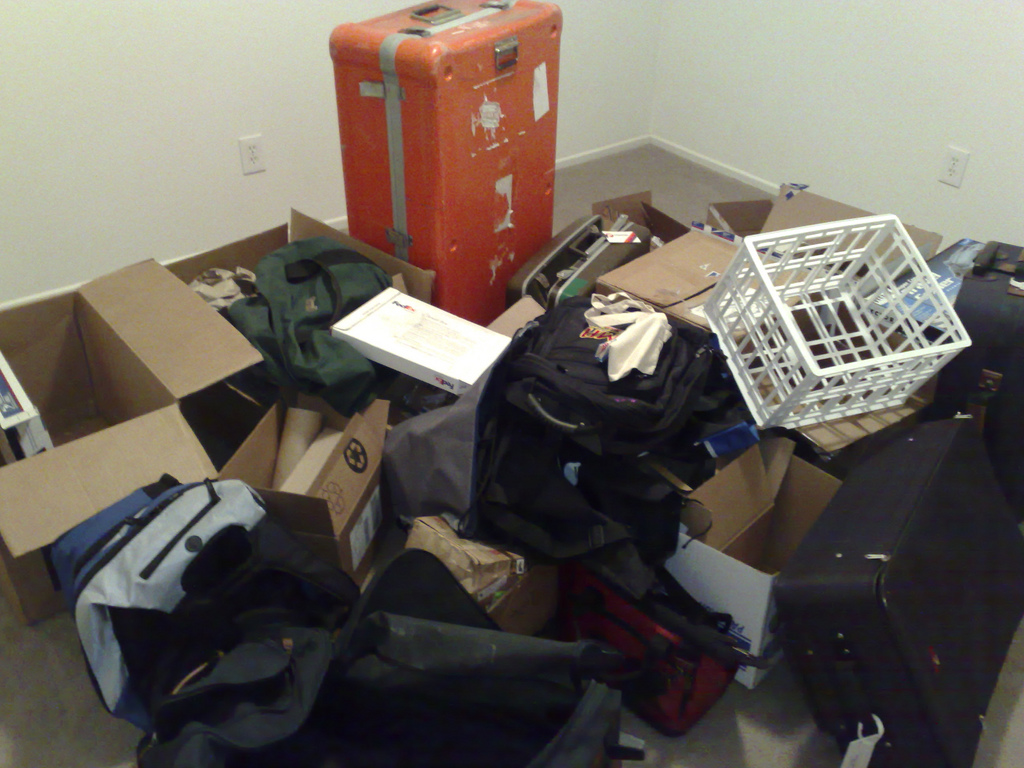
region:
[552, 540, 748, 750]
Red hand bag on a floor.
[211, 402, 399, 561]
Cardboard box on a floor.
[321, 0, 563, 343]
Orange case next to a pile of bags.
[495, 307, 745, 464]
Black bag on a pile of bags.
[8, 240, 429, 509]
Cardboard boxes on a floor.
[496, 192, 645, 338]
Brown suitcase on the floor.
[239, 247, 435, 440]
Green bag on top of a box.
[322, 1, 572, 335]
a large orange hard suitcase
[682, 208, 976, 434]
an empty white plastic container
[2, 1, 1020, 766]
a room filled with luggage and boxes on the floor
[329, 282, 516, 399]
a small white FedEx box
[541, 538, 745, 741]
a small black and red bag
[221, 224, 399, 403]
an empty green duffel bag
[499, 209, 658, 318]
a partly open brown suitcase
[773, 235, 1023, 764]
two dark blue suitcases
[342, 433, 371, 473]
a small circle recycle sign on brown box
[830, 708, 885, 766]
a white tag on the handle of a suitcase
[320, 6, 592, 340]
suitcase behind pile in room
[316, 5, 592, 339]
suitcase behind pile is orange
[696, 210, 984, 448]
small basket is white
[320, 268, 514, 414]
small shipping box on pile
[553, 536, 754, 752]
small red bag on ground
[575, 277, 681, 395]
wadded paper on pile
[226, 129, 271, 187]
white outlet on wall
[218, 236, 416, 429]
empty bag is green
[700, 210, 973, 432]
plastic basket is on top of box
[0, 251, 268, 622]
box is on the ground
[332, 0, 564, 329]
case is orange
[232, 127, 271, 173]
outlet is apart of the wall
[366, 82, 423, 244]
Stripe on a box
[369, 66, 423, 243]
Silver stripe on a box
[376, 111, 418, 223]
Stripe on a box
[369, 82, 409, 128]
Stripe on a box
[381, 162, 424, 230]
Stripe on a box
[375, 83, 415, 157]
Stripe on a box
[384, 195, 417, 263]
Stripe on a box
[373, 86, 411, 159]
Stripe on a box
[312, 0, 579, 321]
an orange suitcase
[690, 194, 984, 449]
the white box is empty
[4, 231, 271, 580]
the box is open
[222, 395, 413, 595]
a small box on the floor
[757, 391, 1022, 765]
the suitcase is black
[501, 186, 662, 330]
the suitcase is open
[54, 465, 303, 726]
a bag on the floor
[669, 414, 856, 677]
an open box on side a suitcase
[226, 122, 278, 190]
an electrical plug on the wall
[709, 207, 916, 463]
a white plastic crate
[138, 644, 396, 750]
a bag on the floor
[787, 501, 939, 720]
a bag on the floor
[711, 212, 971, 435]
the crate is white in color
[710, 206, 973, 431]
the crate is made of plastic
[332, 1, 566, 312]
the suitcase is red in color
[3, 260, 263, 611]
the box is open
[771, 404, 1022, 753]
the suitcase is black in color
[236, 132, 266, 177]
a wall outlet is white in color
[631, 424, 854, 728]
A box on the ground.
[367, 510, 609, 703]
A box on the ground.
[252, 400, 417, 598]
A box on the ground.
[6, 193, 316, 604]
A box on the ground.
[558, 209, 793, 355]
A box on the ground.